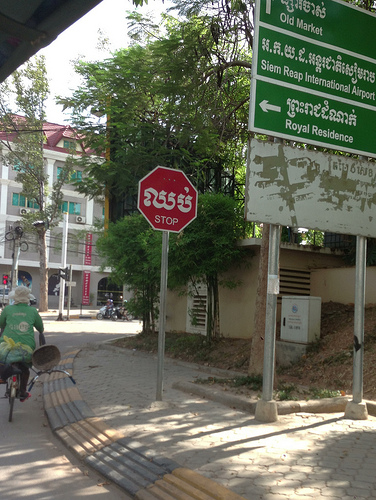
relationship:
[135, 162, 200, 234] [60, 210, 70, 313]
sign attached pole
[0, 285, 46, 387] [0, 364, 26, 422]
human carrying bicycle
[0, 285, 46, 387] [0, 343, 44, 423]
human riding bicycle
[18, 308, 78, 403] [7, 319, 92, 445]
basket attached bicycle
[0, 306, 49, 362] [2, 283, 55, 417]
top worn human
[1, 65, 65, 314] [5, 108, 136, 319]
tree in background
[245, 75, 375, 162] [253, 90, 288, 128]
sign gives directions